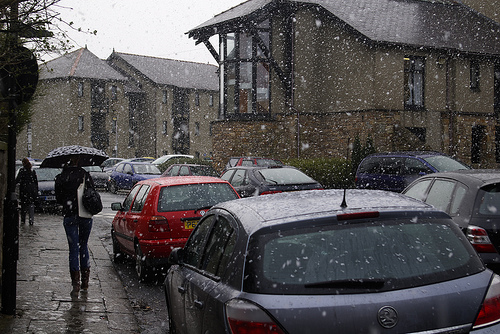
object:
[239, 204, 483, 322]
rear view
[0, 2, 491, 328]
day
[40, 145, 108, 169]
umbrella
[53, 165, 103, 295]
woman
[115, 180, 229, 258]
car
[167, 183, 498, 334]
cars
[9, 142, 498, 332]
street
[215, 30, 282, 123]
balcony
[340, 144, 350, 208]
antennae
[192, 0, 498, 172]
houses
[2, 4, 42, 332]
stop light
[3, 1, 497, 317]
snow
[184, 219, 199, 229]
plate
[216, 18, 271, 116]
window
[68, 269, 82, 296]
boots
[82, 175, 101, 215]
purse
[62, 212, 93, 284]
jeans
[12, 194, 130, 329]
sidewalk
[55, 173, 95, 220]
jacket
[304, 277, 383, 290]
wiper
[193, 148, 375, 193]
bushes